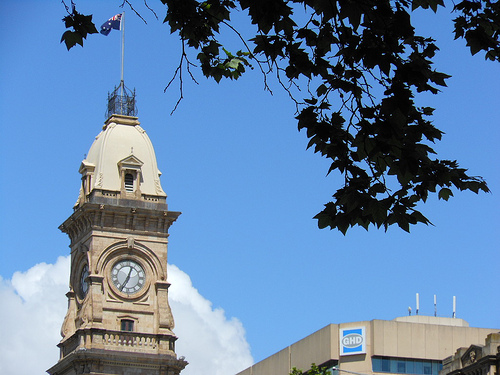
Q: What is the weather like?
A: It is clear.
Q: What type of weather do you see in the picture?
A: It is clear.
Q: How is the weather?
A: It is clear.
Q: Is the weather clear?
A: Yes, it is clear.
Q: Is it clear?
A: Yes, it is clear.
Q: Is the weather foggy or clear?
A: It is clear.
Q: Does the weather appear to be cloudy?
A: No, it is clear.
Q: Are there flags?
A: Yes, there is a flag.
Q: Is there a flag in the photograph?
A: Yes, there is a flag.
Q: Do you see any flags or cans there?
A: Yes, there is a flag.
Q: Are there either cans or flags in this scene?
A: Yes, there is a flag.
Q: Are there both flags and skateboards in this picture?
A: No, there is a flag but no skateboards.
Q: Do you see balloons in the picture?
A: No, there are no balloons.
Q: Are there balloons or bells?
A: No, there are no balloons or bells.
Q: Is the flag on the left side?
A: Yes, the flag is on the left of the image.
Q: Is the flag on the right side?
A: No, the flag is on the left of the image.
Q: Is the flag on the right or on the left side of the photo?
A: The flag is on the left of the image.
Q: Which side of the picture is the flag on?
A: The flag is on the left of the image.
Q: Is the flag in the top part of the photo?
A: Yes, the flag is in the top of the image.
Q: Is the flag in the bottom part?
A: No, the flag is in the top of the image.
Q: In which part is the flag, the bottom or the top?
A: The flag is in the top of the image.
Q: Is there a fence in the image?
A: No, there are no fences.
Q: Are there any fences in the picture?
A: No, there are no fences.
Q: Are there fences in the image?
A: No, there are no fences.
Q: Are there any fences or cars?
A: No, there are no fences or cars.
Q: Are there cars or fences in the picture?
A: No, there are no fences or cars.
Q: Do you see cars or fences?
A: No, there are no fences or cars.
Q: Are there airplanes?
A: No, there are no airplanes.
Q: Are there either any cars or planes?
A: No, there are no planes or cars.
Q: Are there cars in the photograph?
A: No, there are no cars.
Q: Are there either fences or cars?
A: No, there are no cars or fences.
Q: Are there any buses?
A: Yes, there is a bus.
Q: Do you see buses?
A: Yes, there is a bus.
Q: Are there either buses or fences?
A: Yes, there is a bus.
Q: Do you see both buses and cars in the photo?
A: No, there is a bus but no cars.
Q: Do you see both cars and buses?
A: No, there is a bus but no cars.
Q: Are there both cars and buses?
A: No, there is a bus but no cars.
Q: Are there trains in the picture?
A: No, there are no trains.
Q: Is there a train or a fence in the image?
A: No, there are no trains or fences.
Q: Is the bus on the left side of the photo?
A: Yes, the bus is on the left of the image.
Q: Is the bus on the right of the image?
A: No, the bus is on the left of the image.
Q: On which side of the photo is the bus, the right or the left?
A: The bus is on the left of the image.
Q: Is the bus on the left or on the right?
A: The bus is on the left of the image.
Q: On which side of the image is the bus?
A: The bus is on the left of the image.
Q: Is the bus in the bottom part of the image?
A: Yes, the bus is in the bottom of the image.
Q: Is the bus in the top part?
A: No, the bus is in the bottom of the image.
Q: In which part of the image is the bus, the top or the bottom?
A: The bus is in the bottom of the image.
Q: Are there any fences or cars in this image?
A: No, there are no fences or cars.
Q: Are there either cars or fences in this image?
A: No, there are no fences or cars.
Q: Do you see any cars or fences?
A: No, there are no fences or cars.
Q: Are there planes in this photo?
A: No, there are no planes.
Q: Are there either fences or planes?
A: No, there are no planes or fences.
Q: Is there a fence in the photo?
A: No, there are no fences.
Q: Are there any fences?
A: No, there are no fences.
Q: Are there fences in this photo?
A: No, there are no fences.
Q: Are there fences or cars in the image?
A: No, there are no fences or cars.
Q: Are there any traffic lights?
A: No, there are no traffic lights.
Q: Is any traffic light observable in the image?
A: No, there are no traffic lights.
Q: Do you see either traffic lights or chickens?
A: No, there are no traffic lights or chickens.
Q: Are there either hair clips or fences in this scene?
A: No, there are no fences or hair clips.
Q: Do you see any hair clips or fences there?
A: No, there are no fences or hair clips.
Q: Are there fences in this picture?
A: No, there are no fences.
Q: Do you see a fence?
A: No, there are no fences.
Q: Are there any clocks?
A: Yes, there is a clock.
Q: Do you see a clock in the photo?
A: Yes, there is a clock.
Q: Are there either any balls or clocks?
A: Yes, there is a clock.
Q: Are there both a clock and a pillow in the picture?
A: No, there is a clock but no pillows.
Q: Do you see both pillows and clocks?
A: No, there is a clock but no pillows.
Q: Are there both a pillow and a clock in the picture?
A: No, there is a clock but no pillows.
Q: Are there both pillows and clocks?
A: No, there is a clock but no pillows.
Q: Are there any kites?
A: No, there are no kites.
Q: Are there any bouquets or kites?
A: No, there are no kites or bouquets.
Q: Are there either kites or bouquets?
A: No, there are no kites or bouquets.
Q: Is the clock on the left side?
A: Yes, the clock is on the left of the image.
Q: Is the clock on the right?
A: No, the clock is on the left of the image.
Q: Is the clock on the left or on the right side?
A: The clock is on the left of the image.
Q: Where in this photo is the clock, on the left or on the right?
A: The clock is on the left of the image.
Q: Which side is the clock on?
A: The clock is on the left of the image.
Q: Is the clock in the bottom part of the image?
A: Yes, the clock is in the bottom of the image.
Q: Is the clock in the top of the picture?
A: No, the clock is in the bottom of the image.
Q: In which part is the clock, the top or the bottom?
A: The clock is in the bottom of the image.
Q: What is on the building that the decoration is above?
A: The clock is on the building.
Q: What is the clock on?
A: The clock is on the building.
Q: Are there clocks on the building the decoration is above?
A: Yes, there is a clock on the building.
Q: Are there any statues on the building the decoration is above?
A: No, there is a clock on the building.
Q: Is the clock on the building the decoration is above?
A: Yes, the clock is on the building.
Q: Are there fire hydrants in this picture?
A: No, there are no fire hydrants.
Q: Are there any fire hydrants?
A: No, there are no fire hydrants.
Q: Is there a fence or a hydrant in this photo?
A: No, there are no fire hydrants or fences.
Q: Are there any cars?
A: No, there are no cars.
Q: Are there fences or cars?
A: No, there are no cars or fences.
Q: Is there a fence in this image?
A: No, there are no fences.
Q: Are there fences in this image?
A: No, there are no fences.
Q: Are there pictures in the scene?
A: No, there are no pictures.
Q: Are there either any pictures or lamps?
A: No, there are no pictures or lamps.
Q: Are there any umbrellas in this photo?
A: No, there are no umbrellas.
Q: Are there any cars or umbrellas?
A: No, there are no umbrellas or cars.